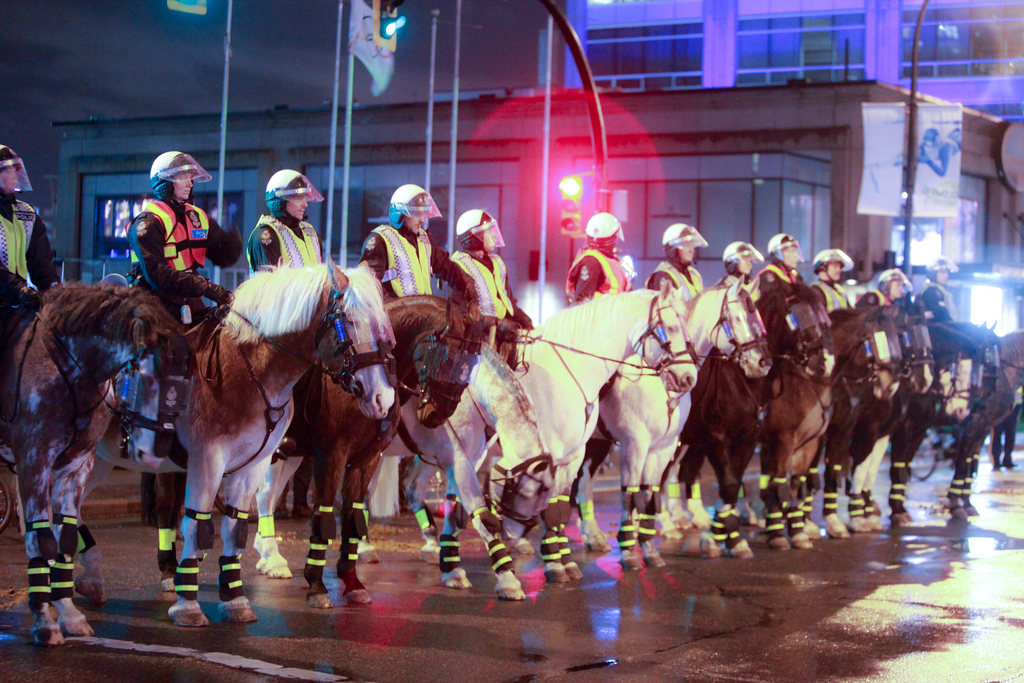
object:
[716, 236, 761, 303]
person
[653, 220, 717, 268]
head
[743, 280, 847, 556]
horse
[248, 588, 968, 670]
road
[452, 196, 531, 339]
person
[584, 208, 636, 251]
head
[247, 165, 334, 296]
person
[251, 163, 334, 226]
head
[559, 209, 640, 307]
person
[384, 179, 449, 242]
head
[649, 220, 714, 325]
person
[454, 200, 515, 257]
head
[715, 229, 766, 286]
head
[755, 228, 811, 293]
person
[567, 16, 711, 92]
windows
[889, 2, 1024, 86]
windows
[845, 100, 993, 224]
sign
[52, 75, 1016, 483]
building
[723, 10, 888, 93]
windows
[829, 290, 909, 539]
horse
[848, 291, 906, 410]
head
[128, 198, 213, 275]
vest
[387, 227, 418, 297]
stripes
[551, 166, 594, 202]
light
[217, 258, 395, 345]
hair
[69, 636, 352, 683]
line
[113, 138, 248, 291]
person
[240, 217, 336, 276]
vest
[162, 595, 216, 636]
hoof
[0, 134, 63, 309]
person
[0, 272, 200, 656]
horse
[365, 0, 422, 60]
traffic light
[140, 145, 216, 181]
helmet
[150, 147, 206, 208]
head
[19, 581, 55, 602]
strip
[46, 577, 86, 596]
strip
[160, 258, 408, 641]
horse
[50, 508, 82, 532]
strip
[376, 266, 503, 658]
horse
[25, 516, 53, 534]
strip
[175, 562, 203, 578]
strip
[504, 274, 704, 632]
horse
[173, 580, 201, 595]
strip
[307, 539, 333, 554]
strip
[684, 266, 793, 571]
horse